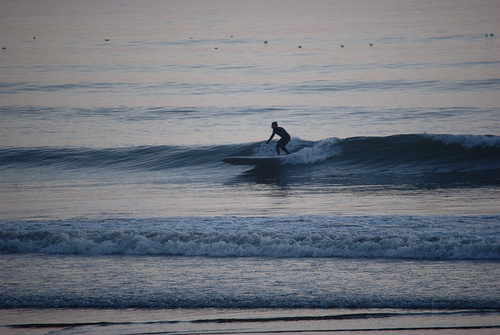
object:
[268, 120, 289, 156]
person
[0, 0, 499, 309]
water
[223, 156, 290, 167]
surfboard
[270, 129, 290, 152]
wetsuit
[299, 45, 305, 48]
object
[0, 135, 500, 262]
wave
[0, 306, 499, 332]
shore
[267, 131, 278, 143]
arm